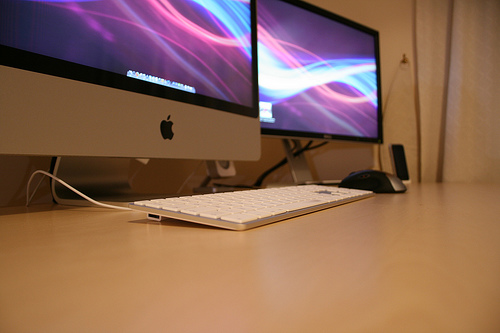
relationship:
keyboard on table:
[129, 179, 384, 249] [0, 174, 497, 331]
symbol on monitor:
[157, 109, 184, 149] [0, 0, 265, 162]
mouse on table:
[338, 167, 406, 195] [2, 185, 498, 325]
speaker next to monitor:
[388, 142, 412, 185] [255, 0, 380, 142]